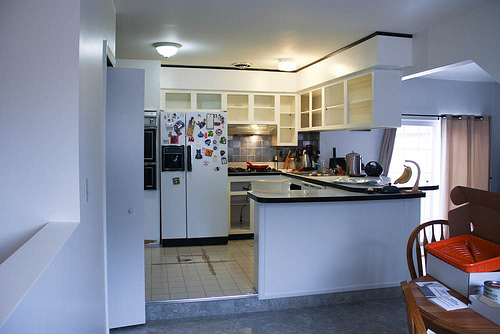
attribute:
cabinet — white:
[321, 85, 345, 122]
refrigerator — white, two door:
[185, 109, 230, 239]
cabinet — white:
[287, 66, 387, 132]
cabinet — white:
[158, 64, 410, 151]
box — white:
[409, 216, 499, 298]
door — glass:
[253, 93, 274, 119]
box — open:
[425, 236, 499, 300]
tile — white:
[143, 235, 255, 300]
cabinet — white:
[194, 90, 225, 109]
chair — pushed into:
[400, 282, 423, 330]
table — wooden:
[399, 258, 499, 330]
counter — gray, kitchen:
[245, 151, 434, 213]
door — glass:
[268, 78, 312, 137]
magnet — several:
[204, 147, 213, 157]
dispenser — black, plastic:
[153, 140, 186, 170]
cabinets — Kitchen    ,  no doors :
[164, 67, 400, 145]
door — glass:
[341, 73, 378, 123]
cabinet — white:
[347, 68, 403, 130]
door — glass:
[345, 75, 374, 125]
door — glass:
[275, 95, 282, 146]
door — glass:
[347, 71, 375, 123]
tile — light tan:
[156, 249, 250, 292]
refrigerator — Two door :
[157, 106, 232, 243]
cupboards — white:
[163, 60, 400, 130]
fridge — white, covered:
[154, 107, 244, 233]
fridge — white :
[152, 106, 234, 248]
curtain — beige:
[441, 108, 481, 176]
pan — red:
[426, 233, 485, 263]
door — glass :
[144, 60, 166, 104]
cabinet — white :
[120, 43, 164, 103]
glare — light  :
[168, 111, 221, 171]